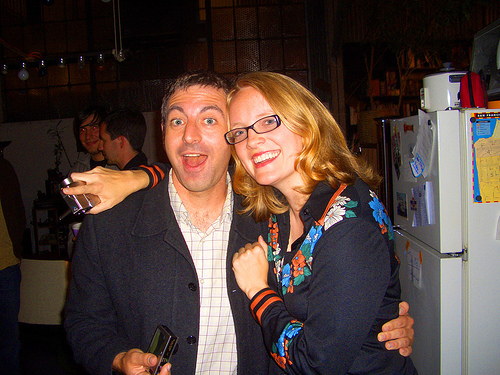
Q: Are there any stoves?
A: No, there are no stoves.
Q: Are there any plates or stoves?
A: No, there are no stoves or plates.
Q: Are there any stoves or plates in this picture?
A: No, there are no stoves or plates.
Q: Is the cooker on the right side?
A: Yes, the cooker is on the right of the image.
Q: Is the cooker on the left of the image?
A: No, the cooker is on the right of the image.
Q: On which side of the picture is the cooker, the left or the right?
A: The cooker is on the right of the image.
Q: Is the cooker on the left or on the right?
A: The cooker is on the right of the image.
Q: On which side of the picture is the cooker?
A: The cooker is on the right of the image.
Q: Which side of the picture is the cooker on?
A: The cooker is on the right of the image.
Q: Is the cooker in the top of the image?
A: Yes, the cooker is in the top of the image.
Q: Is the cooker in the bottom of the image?
A: No, the cooker is in the top of the image.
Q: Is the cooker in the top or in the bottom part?
A: The cooker is in the top of the image.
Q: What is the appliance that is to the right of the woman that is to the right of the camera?
A: The appliance is a cooker.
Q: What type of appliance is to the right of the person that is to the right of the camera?
A: The appliance is a cooker.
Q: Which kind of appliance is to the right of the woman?
A: The appliance is a cooker.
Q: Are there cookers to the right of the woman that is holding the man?
A: Yes, there is a cooker to the right of the woman.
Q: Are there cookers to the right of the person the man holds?
A: Yes, there is a cooker to the right of the woman.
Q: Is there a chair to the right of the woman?
A: No, there is a cooker to the right of the woman.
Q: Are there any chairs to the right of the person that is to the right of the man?
A: No, there is a cooker to the right of the woman.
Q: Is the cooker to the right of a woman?
A: Yes, the cooker is to the right of a woman.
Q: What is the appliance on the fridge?
A: The appliance is a cooker.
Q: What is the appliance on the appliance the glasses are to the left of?
A: The appliance is a cooker.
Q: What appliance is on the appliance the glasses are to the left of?
A: The appliance is a cooker.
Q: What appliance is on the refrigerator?
A: The appliance is a cooker.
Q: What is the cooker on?
A: The cooker is on the refrigerator.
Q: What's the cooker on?
A: The cooker is on the refrigerator.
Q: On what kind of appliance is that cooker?
A: The cooker is on the refrigerator.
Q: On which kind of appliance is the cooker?
A: The cooker is on the refrigerator.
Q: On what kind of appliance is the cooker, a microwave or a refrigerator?
A: The cooker is on a refrigerator.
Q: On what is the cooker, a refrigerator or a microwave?
A: The cooker is on a refrigerator.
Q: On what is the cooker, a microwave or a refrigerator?
A: The cooker is on a refrigerator.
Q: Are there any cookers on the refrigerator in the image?
A: Yes, there is a cooker on the refrigerator.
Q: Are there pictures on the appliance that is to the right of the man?
A: No, there is a cooker on the fridge.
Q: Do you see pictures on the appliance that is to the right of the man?
A: No, there is a cooker on the fridge.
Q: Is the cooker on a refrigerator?
A: Yes, the cooker is on a refrigerator.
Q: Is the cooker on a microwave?
A: No, the cooker is on a refrigerator.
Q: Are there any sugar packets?
A: No, there are no sugar packets.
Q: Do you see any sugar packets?
A: No, there are no sugar packets.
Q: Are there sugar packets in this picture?
A: No, there are no sugar packets.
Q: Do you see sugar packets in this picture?
A: No, there are no sugar packets.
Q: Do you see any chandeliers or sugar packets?
A: No, there are no sugar packets or chandeliers.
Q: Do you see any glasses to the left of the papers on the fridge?
A: Yes, there are glasses to the left of the papers.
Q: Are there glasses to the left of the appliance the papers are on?
A: Yes, there are glasses to the left of the freezer.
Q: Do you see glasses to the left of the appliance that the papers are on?
A: Yes, there are glasses to the left of the freezer.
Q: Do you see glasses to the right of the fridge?
A: No, the glasses are to the left of the fridge.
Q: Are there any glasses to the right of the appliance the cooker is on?
A: No, the glasses are to the left of the fridge.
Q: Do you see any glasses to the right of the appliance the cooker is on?
A: No, the glasses are to the left of the fridge.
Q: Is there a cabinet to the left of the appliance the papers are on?
A: No, there are glasses to the left of the refrigerator.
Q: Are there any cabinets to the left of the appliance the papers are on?
A: No, there are glasses to the left of the refrigerator.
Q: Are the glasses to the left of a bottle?
A: No, the glasses are to the left of the fridge.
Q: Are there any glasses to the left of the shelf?
A: Yes, there are glasses to the left of the shelf.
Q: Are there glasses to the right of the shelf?
A: No, the glasses are to the left of the shelf.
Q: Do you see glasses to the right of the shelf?
A: No, the glasses are to the left of the shelf.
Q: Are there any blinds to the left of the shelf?
A: No, there are glasses to the left of the shelf.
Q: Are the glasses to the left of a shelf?
A: Yes, the glasses are to the left of a shelf.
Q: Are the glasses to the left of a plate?
A: No, the glasses are to the left of a shelf.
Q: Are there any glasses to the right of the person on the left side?
A: Yes, there are glasses to the right of the person.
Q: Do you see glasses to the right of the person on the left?
A: Yes, there are glasses to the right of the person.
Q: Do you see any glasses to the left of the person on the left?
A: No, the glasses are to the right of the person.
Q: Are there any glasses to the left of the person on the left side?
A: No, the glasses are to the right of the person.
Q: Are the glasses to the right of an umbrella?
A: No, the glasses are to the right of the person.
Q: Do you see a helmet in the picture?
A: No, there are no helmets.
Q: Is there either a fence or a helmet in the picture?
A: No, there are no helmets or fences.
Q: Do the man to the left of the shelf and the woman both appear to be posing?
A: Yes, both the man and the woman are posing.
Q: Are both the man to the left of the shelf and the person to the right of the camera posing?
A: Yes, both the man and the woman are posing.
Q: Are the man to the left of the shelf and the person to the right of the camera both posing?
A: Yes, both the man and the woman are posing.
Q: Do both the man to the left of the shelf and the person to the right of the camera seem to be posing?
A: Yes, both the man and the woman are posing.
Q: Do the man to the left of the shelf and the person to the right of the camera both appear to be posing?
A: Yes, both the man and the woman are posing.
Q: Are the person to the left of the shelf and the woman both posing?
A: Yes, both the man and the woman are posing.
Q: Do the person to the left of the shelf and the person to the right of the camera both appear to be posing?
A: Yes, both the man and the woman are posing.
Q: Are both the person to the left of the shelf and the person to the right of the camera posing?
A: Yes, both the man and the woman are posing.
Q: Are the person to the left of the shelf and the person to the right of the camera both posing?
A: Yes, both the man and the woman are posing.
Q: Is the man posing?
A: Yes, the man is posing.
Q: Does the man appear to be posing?
A: Yes, the man is posing.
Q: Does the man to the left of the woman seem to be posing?
A: Yes, the man is posing.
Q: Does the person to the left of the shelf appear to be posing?
A: Yes, the man is posing.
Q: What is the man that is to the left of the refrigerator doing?
A: The man is posing.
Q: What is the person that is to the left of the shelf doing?
A: The man is posing.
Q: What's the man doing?
A: The man is posing.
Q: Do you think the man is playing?
A: No, the man is posing.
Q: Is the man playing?
A: No, the man is posing.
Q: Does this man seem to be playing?
A: No, the man is posing.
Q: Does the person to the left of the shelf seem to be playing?
A: No, the man is posing.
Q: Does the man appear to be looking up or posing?
A: The man is posing.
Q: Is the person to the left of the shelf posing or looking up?
A: The man is posing.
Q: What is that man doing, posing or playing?
A: The man is posing.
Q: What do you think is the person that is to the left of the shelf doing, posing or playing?
A: The man is posing.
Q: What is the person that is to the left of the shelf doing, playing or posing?
A: The man is posing.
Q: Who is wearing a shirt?
A: The man is wearing a shirt.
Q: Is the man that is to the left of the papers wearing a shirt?
A: Yes, the man is wearing a shirt.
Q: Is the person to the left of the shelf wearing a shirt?
A: Yes, the man is wearing a shirt.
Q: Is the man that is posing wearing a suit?
A: No, the man is wearing a shirt.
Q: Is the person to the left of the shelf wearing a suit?
A: No, the man is wearing a shirt.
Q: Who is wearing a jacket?
A: The man is wearing a jacket.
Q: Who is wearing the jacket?
A: The man is wearing a jacket.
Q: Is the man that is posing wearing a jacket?
A: Yes, the man is wearing a jacket.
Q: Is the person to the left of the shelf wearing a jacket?
A: Yes, the man is wearing a jacket.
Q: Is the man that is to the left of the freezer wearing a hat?
A: No, the man is wearing a jacket.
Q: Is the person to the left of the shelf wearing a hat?
A: No, the man is wearing a jacket.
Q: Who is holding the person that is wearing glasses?
A: The man is holding the woman.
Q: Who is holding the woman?
A: The man is holding the woman.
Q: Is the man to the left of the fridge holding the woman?
A: Yes, the man is holding the woman.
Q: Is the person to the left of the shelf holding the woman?
A: Yes, the man is holding the woman.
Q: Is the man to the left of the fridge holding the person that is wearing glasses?
A: Yes, the man is holding the woman.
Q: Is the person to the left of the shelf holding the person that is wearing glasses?
A: Yes, the man is holding the woman.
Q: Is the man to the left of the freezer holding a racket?
A: No, the man is holding the woman.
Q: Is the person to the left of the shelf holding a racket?
A: No, the man is holding the woman.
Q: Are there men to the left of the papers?
A: Yes, there is a man to the left of the papers.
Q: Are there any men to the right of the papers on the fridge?
A: No, the man is to the left of the papers.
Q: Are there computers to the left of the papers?
A: No, there is a man to the left of the papers.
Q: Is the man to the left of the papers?
A: Yes, the man is to the left of the papers.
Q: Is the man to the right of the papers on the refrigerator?
A: No, the man is to the left of the papers.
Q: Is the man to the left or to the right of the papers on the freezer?
A: The man is to the left of the papers.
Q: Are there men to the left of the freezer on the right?
A: Yes, there is a man to the left of the fridge.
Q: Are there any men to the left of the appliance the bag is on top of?
A: Yes, there is a man to the left of the fridge.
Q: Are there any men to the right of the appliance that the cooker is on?
A: No, the man is to the left of the refrigerator.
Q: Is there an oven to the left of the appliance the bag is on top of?
A: No, there is a man to the left of the fridge.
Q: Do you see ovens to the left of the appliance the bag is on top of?
A: No, there is a man to the left of the fridge.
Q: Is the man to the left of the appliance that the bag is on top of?
A: Yes, the man is to the left of the freezer.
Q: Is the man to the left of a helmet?
A: No, the man is to the left of the freezer.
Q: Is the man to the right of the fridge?
A: No, the man is to the left of the fridge.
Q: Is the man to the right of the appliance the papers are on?
A: No, the man is to the left of the fridge.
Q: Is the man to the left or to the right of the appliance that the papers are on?
A: The man is to the left of the refrigerator.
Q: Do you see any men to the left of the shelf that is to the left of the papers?
A: Yes, there is a man to the left of the shelf.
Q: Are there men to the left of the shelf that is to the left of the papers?
A: Yes, there is a man to the left of the shelf.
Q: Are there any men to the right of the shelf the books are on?
A: No, the man is to the left of the shelf.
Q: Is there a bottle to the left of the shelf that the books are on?
A: No, there is a man to the left of the shelf.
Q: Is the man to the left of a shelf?
A: Yes, the man is to the left of a shelf.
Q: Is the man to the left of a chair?
A: No, the man is to the left of a shelf.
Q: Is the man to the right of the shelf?
A: No, the man is to the left of the shelf.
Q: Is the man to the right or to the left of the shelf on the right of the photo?
A: The man is to the left of the shelf.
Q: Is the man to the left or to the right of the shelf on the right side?
A: The man is to the left of the shelf.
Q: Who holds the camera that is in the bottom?
A: The man holds the camera.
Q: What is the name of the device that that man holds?
A: The device is a camera.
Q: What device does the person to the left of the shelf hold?
A: The man holds the camera.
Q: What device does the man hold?
A: The man holds the camera.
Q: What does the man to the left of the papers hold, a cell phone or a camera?
A: The man holds a camera.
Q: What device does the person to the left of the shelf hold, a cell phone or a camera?
A: The man holds a camera.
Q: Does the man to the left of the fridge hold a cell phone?
A: No, the man holds the camera.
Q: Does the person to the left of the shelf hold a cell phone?
A: No, the man holds the camera.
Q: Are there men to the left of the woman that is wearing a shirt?
A: Yes, there is a man to the left of the woman.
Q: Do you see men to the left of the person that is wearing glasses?
A: Yes, there is a man to the left of the woman.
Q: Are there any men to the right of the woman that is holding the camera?
A: No, the man is to the left of the woman.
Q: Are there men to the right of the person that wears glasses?
A: No, the man is to the left of the woman.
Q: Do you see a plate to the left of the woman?
A: No, there is a man to the left of the woman.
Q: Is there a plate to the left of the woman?
A: No, there is a man to the left of the woman.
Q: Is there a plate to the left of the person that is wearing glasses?
A: No, there is a man to the left of the woman.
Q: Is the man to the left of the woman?
A: Yes, the man is to the left of the woman.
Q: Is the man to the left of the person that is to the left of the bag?
A: Yes, the man is to the left of the woman.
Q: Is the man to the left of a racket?
A: No, the man is to the left of the woman.